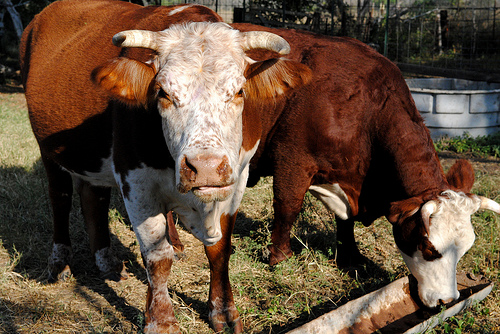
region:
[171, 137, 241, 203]
a brown cow nose.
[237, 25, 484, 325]
a cow standing in a field.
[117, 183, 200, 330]
the right leg of a cow.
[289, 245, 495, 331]
a water trough in front of a cow.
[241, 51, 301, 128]
a left cow ear.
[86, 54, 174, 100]
right ear of a cow.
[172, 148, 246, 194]
a nose on a cow.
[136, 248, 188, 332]
a right cow leg.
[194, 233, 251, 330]
a left cow leg.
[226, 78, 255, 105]
a left cow eye.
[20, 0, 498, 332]
Pair of brown and white cows.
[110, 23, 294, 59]
Horns of a cow.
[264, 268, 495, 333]
Metal dish with water for drinking.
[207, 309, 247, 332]
Hooves of a cow.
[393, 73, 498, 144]
Plastic white container.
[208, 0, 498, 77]
Wire fence with green poles.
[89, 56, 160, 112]
Furry brown ear of a cow.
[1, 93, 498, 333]
Green and brown grass.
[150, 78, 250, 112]
Pair of cows eyes.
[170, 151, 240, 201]
Wet nose and mouth of a cow.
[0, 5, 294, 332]
this is a cow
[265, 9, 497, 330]
this is a cow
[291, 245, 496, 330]
this is a feeding trough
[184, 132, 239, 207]
the mouth of a cow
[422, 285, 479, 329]
the mouth of a cow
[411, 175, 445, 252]
this is a horn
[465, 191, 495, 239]
this is a horn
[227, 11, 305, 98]
this is a horn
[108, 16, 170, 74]
this is a horn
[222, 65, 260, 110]
this is an eye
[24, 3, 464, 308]
the cows on the grass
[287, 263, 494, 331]
the trough on the grass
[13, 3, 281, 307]
the cow is brown and white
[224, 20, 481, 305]
the cow is brown and white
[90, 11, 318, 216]
the head of the cow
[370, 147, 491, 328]
the head of the cow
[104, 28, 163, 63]
the horn of the cow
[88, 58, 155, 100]
the ear of the cow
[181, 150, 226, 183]
the nose of the cow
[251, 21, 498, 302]
the cow is eating